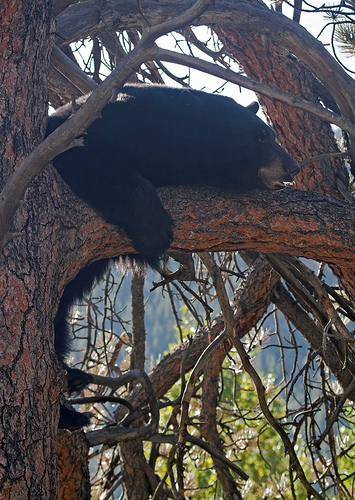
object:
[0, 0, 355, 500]
pine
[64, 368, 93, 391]
foot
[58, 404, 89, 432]
foot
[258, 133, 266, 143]
eye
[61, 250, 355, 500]
branches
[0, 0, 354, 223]
branch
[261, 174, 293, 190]
mouth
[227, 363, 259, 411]
foliage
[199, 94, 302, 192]
head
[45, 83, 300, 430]
bear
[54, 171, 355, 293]
limb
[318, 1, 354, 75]
branch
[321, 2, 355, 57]
pine needles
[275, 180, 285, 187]
tongue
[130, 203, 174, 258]
paw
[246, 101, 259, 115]
ear